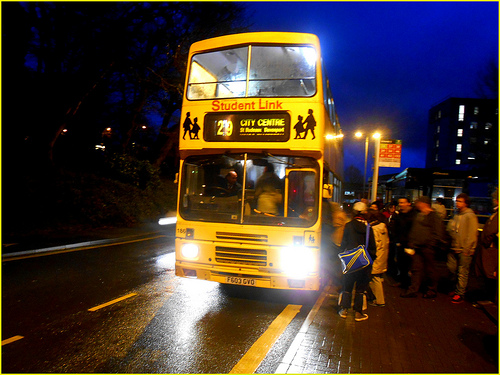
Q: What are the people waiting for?
A: Bus.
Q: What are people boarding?
A: Bus.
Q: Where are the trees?
A: Side of road.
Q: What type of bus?
A: Double decker.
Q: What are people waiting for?
A: Bus.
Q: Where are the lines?
A: On street.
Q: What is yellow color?
A: Bus.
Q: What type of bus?
A: Double decker.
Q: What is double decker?
A: Bus.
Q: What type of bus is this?
A: A double decker bus.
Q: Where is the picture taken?
A: On the street.